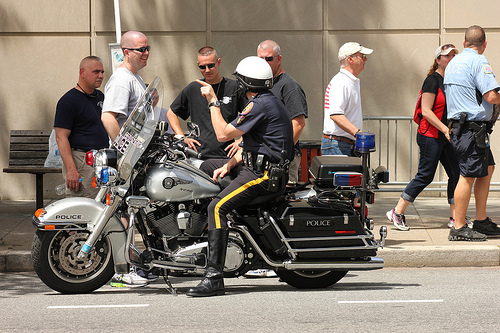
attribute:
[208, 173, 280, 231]
stripe — yellow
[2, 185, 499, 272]
sidewalk — part of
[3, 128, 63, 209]
bench — wooden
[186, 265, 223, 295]
boot — black, man's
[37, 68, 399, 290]
motorcycle — police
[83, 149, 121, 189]
lights — red, blue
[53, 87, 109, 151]
shirt — black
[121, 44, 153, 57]
sun glasses — dark colored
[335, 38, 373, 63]
baseball cap — white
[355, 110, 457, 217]
barrier — metal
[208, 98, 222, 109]
watch — man's black 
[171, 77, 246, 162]
shirt — black 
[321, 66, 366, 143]
shirt — white 